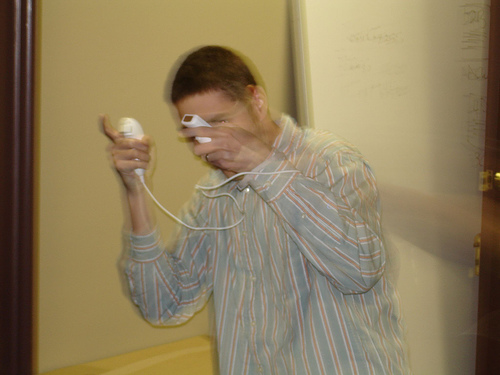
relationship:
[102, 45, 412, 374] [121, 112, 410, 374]
man wearing shirt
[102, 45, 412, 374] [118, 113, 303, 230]
man holding controllers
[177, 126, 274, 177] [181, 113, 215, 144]
hand holding wiimote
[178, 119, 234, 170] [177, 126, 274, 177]
fingers on hand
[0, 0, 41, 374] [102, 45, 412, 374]
wood near man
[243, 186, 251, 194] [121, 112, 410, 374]
button on shirt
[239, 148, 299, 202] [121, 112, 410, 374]
cuff on shirt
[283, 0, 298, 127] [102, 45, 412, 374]
shadow behind man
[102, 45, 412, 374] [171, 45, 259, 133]
man has hair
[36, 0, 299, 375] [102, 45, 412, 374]
wall behind man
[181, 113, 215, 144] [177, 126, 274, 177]
wiimote in hand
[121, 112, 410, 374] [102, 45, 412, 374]
shirt on man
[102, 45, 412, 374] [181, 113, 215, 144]
man holding wiimote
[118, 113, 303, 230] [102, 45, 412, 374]
controllers held by man